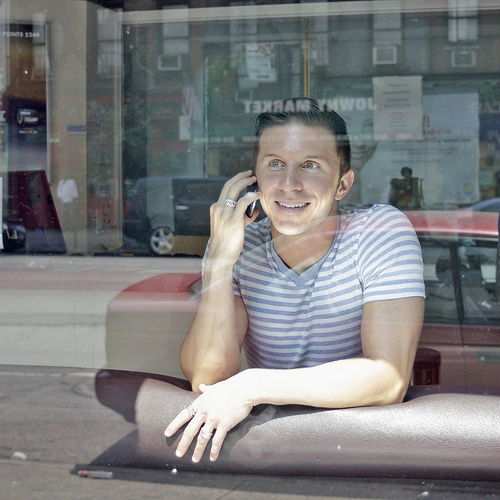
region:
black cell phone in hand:
[208, 161, 260, 254]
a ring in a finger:
[220, 175, 245, 216]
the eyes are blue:
[260, 148, 326, 177]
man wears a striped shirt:
[158, 92, 440, 475]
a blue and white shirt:
[198, 201, 431, 385]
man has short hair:
[196, 93, 403, 300]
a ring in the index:
[160, 392, 198, 422]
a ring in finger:
[196, 420, 215, 455]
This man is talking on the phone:
[201, 81, 396, 267]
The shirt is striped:
[186, 198, 441, 372]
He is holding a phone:
[166, 138, 281, 253]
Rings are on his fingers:
[163, 390, 233, 462]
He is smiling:
[254, 182, 329, 240]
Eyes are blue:
[248, 143, 350, 188]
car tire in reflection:
[149, 222, 176, 252]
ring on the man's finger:
[223, 199, 235, 211]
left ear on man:
[340, 167, 354, 204]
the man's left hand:
[172, 374, 273, 459]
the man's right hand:
[197, 171, 259, 262]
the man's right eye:
[265, 156, 283, 171]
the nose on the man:
[279, 167, 299, 193]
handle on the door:
[176, 200, 188, 216]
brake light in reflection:
[119, 194, 131, 221]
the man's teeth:
[275, 200, 308, 212]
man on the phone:
[155, 83, 444, 468]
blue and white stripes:
[206, 203, 441, 390]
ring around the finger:
[182, 401, 197, 417]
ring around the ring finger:
[221, 193, 239, 208]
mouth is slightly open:
[271, 198, 313, 210]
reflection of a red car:
[76, 185, 499, 417]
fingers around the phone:
[224, 156, 278, 233]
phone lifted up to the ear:
[215, 162, 278, 235]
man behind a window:
[1, 0, 498, 490]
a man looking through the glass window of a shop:
[21, 16, 466, 468]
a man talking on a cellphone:
[195, 100, 360, 244]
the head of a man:
[240, 90, 356, 245]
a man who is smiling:
[231, 88, 371, 257]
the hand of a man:
[160, 373, 257, 478]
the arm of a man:
[241, 283, 422, 467]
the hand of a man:
[196, 167, 261, 267]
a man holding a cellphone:
[199, 160, 265, 262]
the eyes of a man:
[263, 152, 328, 177]